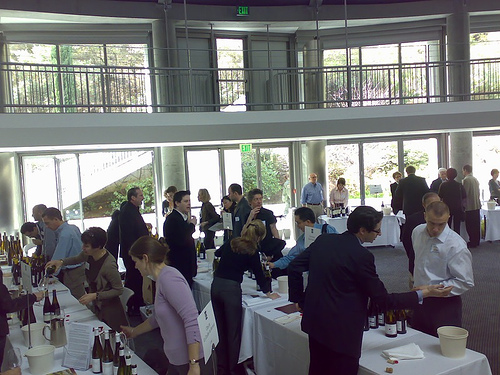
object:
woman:
[121, 236, 209, 375]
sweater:
[147, 267, 205, 365]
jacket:
[288, 230, 420, 333]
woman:
[46, 226, 126, 335]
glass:
[34, 278, 50, 306]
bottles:
[395, 301, 408, 335]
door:
[56, 151, 85, 235]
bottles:
[384, 301, 397, 339]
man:
[163, 191, 198, 292]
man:
[42, 207, 86, 301]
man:
[301, 173, 327, 224]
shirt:
[51, 221, 86, 271]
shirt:
[329, 186, 348, 209]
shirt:
[246, 207, 278, 242]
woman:
[205, 220, 283, 375]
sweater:
[59, 250, 124, 310]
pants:
[210, 278, 243, 374]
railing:
[0, 57, 500, 113]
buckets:
[437, 325, 470, 358]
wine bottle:
[100, 330, 114, 375]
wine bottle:
[90, 328, 104, 374]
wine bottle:
[43, 289, 54, 323]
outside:
[0, 34, 500, 222]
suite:
[287, 230, 426, 375]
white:
[241, 273, 309, 374]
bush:
[241, 147, 291, 205]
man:
[413, 201, 476, 341]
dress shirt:
[412, 222, 475, 296]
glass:
[124, 338, 135, 360]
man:
[285, 207, 453, 375]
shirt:
[273, 223, 340, 270]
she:
[46, 227, 131, 342]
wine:
[44, 265, 56, 278]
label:
[385, 323, 397, 335]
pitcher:
[42, 317, 68, 348]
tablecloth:
[238, 275, 308, 375]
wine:
[42, 289, 53, 324]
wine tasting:
[0, 0, 499, 375]